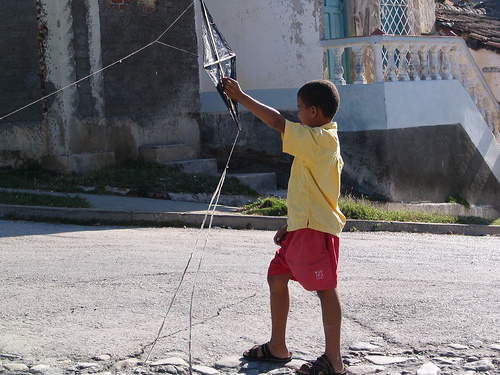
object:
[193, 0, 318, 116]
wall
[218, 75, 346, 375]
boy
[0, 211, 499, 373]
road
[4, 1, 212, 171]
wall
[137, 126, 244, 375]
tail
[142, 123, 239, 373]
string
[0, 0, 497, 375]
photo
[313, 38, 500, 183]
staircase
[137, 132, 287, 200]
staircase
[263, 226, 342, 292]
red shorts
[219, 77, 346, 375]
body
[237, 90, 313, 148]
arm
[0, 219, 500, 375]
concrete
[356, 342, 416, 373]
rocks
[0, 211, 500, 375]
ground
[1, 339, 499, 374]
broken cement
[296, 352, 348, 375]
brown sandal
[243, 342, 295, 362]
brown sandal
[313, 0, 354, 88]
door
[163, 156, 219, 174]
steps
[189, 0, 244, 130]
kite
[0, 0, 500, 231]
background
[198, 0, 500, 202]
building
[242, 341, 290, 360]
feet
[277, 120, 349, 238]
shirt